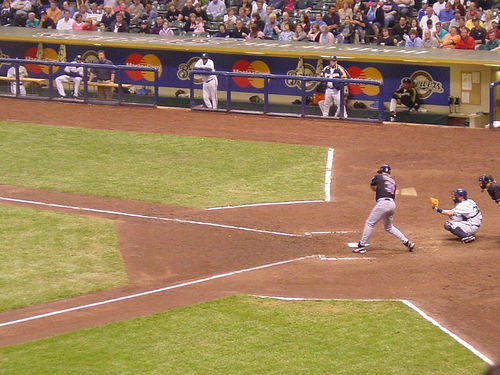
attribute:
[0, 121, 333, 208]
grass — green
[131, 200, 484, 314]
field — dirt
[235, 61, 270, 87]
sign — red and yellow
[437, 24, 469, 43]
person — one